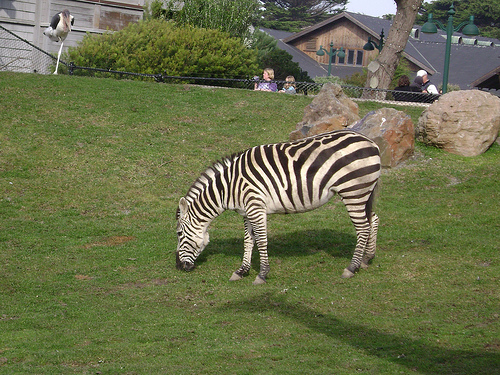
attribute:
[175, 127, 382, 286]
zebra — grazing, black, white, eating, walking, gray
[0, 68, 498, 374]
grass — green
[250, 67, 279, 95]
woman — walking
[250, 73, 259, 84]
camera — filming, taking pictures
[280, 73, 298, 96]
girl — walking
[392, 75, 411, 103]
person — walking, talking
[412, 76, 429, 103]
person — walking, talking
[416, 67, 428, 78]
cap — white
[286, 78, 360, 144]
boulder — brown, large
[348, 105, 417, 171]
boulder — brown, large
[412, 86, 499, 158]
boulder — brown, large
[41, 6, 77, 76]
bird — large, walking, standing, brown, black, white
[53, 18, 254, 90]
bush — large, green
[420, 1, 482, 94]
lamp — green, metal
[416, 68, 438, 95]
person — walking, talking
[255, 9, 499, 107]
building — brown, black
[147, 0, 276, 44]
bush — green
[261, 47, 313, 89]
bush — green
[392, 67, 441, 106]
people — talking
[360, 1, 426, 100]
tree — brown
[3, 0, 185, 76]
building — white